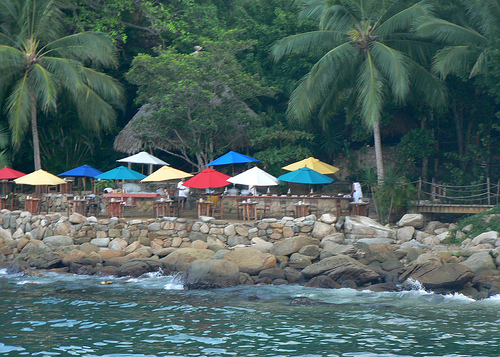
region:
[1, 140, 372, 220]
colored open umbrellas are at each table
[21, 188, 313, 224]
the tables are wooden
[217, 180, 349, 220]
a serving table is behind the tables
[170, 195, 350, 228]
wooden chairs are around the tables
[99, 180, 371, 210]
people are preparing for customers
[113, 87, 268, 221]
a thatched hut is behind the tables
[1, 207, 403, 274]
a rock wall is behind boulders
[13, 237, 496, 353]
the ocean waves are breaking on the rocks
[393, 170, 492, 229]
a wooden bridge is next to the bar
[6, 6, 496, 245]
coconut palms are over the restaurant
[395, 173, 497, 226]
bridge crossing a stream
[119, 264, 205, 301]
waves crashing into the rocks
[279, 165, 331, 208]
blue umbrella near the ocean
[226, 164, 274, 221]
white umbrella at the bar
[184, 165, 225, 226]
red umbrella at the bar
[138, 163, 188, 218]
yellow umbrella near the ocean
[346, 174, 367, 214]
bartender in a white uniform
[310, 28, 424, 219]
palm tree near the ocean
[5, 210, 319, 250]
stone wall on the beach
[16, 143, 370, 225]
umbrellas at an oceanside bar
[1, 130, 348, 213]
The umbrellas are lined up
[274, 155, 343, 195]
The umbrellas are yellow and blue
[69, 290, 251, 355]
The water has waves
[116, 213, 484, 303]
The rocks are near the water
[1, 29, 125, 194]
The palm trees are tall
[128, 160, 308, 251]
The people are standing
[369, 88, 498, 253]
The bridge has ropes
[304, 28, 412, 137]
The palm trees have long leaves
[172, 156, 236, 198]
The umbrella is red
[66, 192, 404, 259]
The side of the wall is stone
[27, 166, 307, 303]
umbrellas and tables near water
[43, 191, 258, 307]
rock wall by water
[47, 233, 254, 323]
water splashing on rocks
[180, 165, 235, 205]
red umbrella over table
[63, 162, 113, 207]
blue umbrella over table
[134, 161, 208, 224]
yellow umbrella over table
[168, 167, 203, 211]
person wearing white shirt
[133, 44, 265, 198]
tree with green leaves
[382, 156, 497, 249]
walkway of wood and rope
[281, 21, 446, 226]
palm tree behind umbrellas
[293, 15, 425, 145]
The palm leaves are long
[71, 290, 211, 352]
The water is dark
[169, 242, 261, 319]
The stones are wet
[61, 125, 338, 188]
The umbrellas are colorful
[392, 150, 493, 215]
The bridge has ropes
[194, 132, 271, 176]
the umbrella is blue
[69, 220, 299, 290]
The wall is made of stone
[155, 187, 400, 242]
The stools are made of wood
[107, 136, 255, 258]
People are standing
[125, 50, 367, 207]
The trees are tall and green